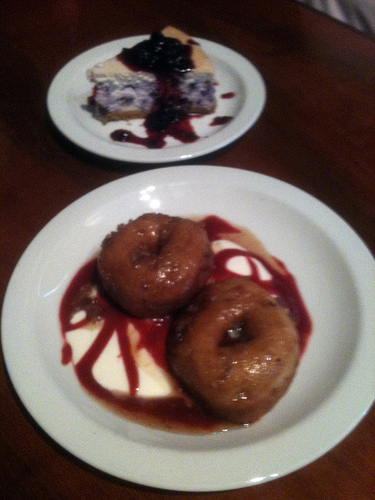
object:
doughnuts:
[164, 277, 304, 430]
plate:
[3, 164, 375, 495]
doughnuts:
[93, 210, 215, 324]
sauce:
[55, 210, 320, 435]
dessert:
[83, 26, 217, 90]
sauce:
[120, 29, 193, 77]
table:
[1, 1, 375, 500]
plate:
[44, 26, 267, 167]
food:
[86, 23, 224, 152]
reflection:
[132, 181, 166, 217]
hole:
[215, 317, 249, 349]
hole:
[146, 236, 165, 259]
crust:
[163, 23, 212, 84]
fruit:
[143, 106, 191, 131]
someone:
[302, 2, 373, 42]